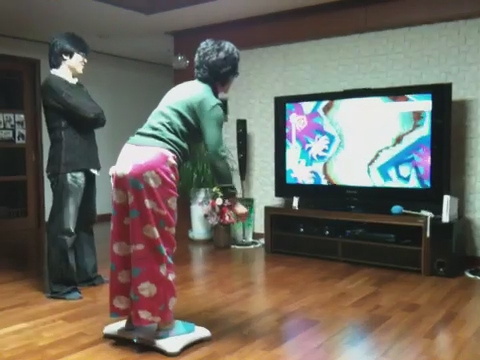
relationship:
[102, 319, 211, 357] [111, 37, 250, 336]
board under woman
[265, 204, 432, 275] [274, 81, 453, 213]
stand holding up tv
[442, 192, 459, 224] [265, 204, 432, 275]
console on stand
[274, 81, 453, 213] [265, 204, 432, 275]
tv on stand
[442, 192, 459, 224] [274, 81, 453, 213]
console beside tv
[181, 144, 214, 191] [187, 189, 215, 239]
plant inside pot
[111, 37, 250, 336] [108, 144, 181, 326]
woman wearing pajamas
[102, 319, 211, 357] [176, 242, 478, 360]
board on floor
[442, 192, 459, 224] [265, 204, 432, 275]
console on top of stand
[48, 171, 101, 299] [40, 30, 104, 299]
pants on man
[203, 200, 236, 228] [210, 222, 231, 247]
flowers in pot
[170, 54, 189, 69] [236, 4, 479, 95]
fixture on wall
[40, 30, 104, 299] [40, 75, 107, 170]
man in shirt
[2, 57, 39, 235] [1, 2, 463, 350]
door leading to another room